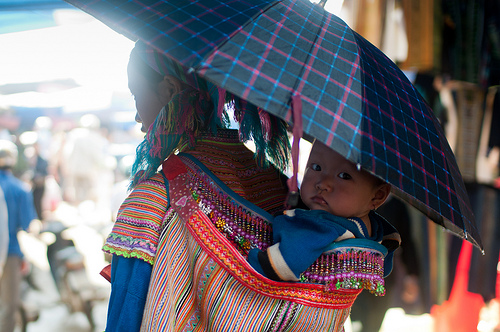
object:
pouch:
[141, 155, 391, 330]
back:
[154, 140, 286, 267]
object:
[423, 222, 500, 332]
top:
[242, 209, 367, 280]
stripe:
[291, 10, 359, 131]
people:
[0, 90, 136, 332]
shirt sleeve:
[101, 247, 154, 330]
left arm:
[102, 169, 180, 332]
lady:
[95, 34, 298, 332]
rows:
[196, 177, 389, 298]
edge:
[175, 137, 391, 260]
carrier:
[124, 161, 381, 331]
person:
[0, 140, 36, 332]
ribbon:
[289, 93, 302, 191]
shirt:
[102, 125, 364, 331]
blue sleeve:
[102, 249, 150, 332]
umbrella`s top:
[68, 0, 485, 254]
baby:
[253, 133, 392, 272]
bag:
[145, 217, 386, 328]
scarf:
[130, 39, 288, 189]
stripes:
[125, 188, 165, 212]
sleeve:
[100, 170, 167, 264]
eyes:
[307, 162, 353, 182]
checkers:
[279, 45, 365, 133]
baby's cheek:
[299, 139, 382, 217]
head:
[126, 40, 230, 138]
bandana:
[127, 40, 213, 187]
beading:
[174, 178, 388, 296]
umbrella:
[69, 0, 484, 247]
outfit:
[251, 201, 373, 286]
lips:
[310, 194, 330, 204]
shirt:
[2, 171, 38, 257]